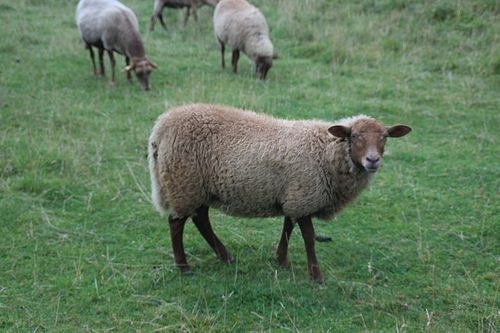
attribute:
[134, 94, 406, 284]
sheep — brown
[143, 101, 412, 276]
sheep — brown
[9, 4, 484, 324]
pasture — green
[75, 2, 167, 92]
sheep — brown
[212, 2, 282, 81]
sheep — brown